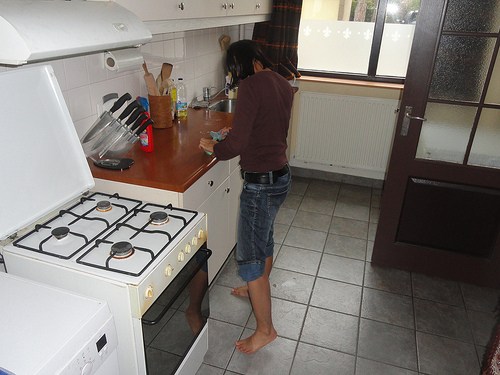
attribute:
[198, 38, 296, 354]
woman — barefoot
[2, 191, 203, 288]
stove — white, gas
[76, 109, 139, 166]
knife block — clear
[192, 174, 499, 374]
floor — tiled, tile, ceramic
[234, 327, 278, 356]
left foot — bare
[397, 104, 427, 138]
handle — silver, metal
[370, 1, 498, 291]
door — open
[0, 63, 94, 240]
cover — white, open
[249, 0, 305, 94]
curtains — dark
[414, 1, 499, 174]
windows — frosted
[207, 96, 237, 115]
sink — stainless steel, metal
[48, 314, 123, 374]
dishwasher — white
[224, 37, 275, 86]
hair — long, black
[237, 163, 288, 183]
belt — black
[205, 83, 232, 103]
faucet — silver, metal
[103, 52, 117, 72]
paper towel — rolled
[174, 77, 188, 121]
bottle — plastic, almost empty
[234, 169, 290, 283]
jeans — blue, rolled up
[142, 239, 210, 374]
door — black, glass